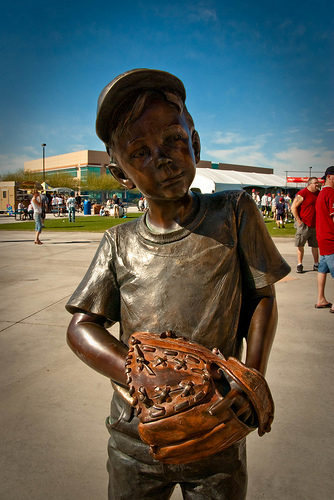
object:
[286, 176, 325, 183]
sign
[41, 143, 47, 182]
light post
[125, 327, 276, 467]
glove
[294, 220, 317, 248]
shorts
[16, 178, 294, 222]
people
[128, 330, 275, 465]
ball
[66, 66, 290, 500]
boy statue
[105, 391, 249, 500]
jeans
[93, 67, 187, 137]
hat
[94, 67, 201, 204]
head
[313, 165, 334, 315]
man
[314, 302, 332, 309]
brown sandals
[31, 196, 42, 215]
shirt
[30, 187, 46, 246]
standing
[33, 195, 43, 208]
crossed arms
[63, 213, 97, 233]
grass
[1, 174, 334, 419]
field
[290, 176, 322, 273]
man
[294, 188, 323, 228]
red shirt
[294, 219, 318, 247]
gray shorts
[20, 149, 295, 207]
building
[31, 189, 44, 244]
person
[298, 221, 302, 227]
hand